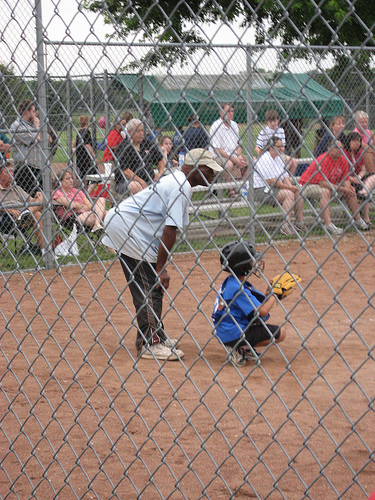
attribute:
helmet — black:
[216, 235, 263, 271]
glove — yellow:
[260, 259, 308, 308]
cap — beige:
[184, 150, 224, 172]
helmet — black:
[217, 237, 264, 278]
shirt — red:
[307, 149, 343, 181]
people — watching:
[41, 78, 272, 173]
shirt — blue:
[211, 273, 269, 343]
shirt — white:
[103, 169, 188, 257]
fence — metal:
[17, 23, 374, 383]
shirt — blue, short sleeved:
[208, 272, 271, 342]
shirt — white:
[206, 115, 241, 164]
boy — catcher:
[209, 238, 305, 367]